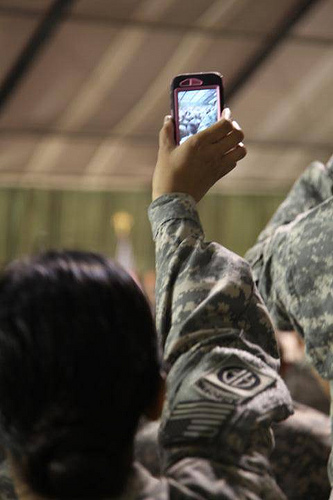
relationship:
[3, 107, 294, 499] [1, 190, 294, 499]
woman wearing army uniform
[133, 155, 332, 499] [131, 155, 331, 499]
person wearing army uniform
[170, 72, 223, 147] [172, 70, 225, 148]
cellphone has case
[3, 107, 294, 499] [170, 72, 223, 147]
woman holding up cellphone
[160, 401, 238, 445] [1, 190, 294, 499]
american flag on top of army uniform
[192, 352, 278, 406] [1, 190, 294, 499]
patch on top of army uniform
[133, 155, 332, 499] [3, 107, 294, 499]
person in front of woman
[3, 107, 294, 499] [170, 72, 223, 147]
woman holding cellphone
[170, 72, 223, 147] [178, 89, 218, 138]
cellphone has screen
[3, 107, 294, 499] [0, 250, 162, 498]
woman has hair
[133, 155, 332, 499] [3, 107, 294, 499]
person next to woman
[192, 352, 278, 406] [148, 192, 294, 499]
patch on top of sleeve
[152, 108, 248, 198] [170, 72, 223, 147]
hand holding cellphone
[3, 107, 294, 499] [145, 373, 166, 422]
woman has ear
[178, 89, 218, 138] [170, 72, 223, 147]
screen on top of cellphone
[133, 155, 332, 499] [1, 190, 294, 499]
person wearing army uniform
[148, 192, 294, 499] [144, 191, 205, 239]
sleeve has cuff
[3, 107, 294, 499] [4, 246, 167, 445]
woman has head